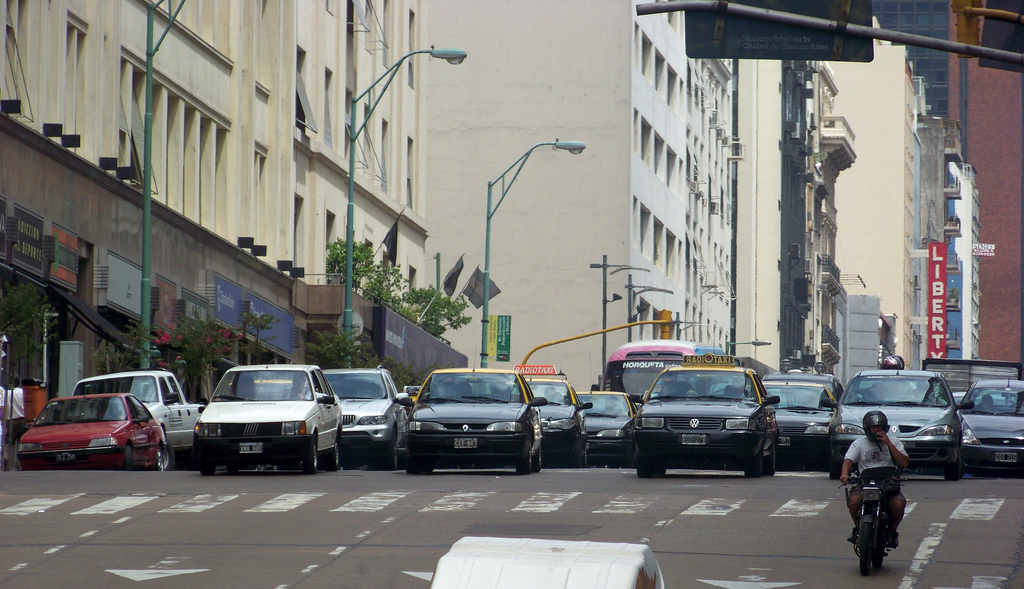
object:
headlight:
[963, 427, 977, 444]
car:
[959, 379, 1020, 477]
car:
[759, 376, 838, 469]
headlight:
[802, 421, 830, 437]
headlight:
[833, 423, 954, 435]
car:
[830, 367, 964, 474]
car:
[629, 354, 779, 477]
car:
[395, 367, 545, 476]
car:
[194, 363, 341, 475]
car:
[318, 368, 413, 470]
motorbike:
[841, 475, 896, 572]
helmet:
[862, 411, 890, 429]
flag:
[380, 216, 400, 267]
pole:
[329, 208, 353, 350]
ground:
[876, 278, 937, 294]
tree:
[321, 238, 375, 282]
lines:
[2, 490, 1017, 513]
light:
[553, 138, 588, 155]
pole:
[477, 183, 490, 368]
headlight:
[485, 420, 521, 432]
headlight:
[640, 415, 667, 428]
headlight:
[282, 420, 306, 435]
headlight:
[17, 441, 44, 455]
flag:
[443, 251, 468, 296]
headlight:
[723, 417, 753, 431]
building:
[811, 20, 945, 372]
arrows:
[74, 519, 235, 586]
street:
[2, 447, 1020, 585]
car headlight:
[640, 418, 749, 429]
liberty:
[920, 233, 948, 366]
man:
[837, 411, 909, 576]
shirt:
[837, 431, 916, 481]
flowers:
[158, 329, 178, 356]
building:
[0, 0, 413, 359]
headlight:
[87, 434, 122, 449]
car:
[14, 394, 164, 471]